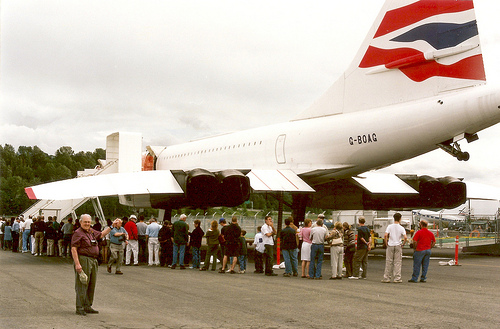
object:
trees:
[0, 143, 22, 214]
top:
[382, 221, 409, 248]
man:
[58, 207, 119, 320]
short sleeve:
[69, 228, 83, 249]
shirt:
[67, 226, 103, 259]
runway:
[0, 250, 497, 328]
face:
[78, 216, 92, 232]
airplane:
[18, 0, 497, 220]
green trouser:
[68, 255, 107, 314]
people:
[301, 214, 331, 286]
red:
[418, 232, 430, 243]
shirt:
[412, 228, 437, 252]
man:
[405, 215, 438, 285]